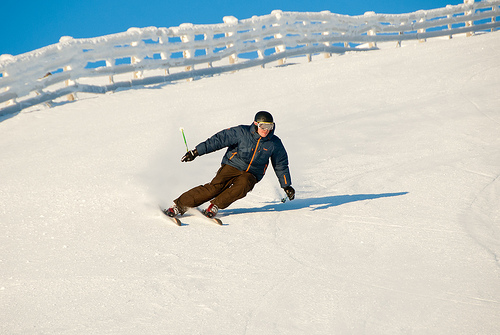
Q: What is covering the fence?
A: Snow.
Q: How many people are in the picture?
A: One.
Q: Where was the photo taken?
A: On a ski slope.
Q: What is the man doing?
A: Skiing.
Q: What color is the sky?
A: Blue.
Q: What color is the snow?
A: White.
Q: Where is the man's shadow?
A: To his right.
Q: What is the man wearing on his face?
A: Goggles.